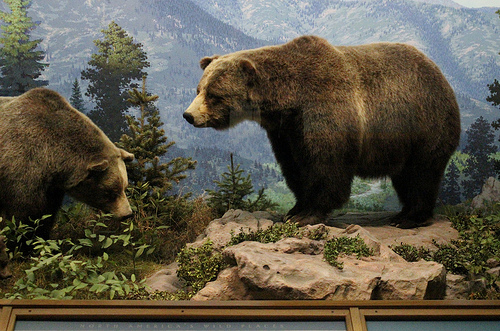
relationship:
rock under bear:
[139, 208, 499, 299] [182, 35, 462, 230]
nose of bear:
[182, 112, 195, 125] [182, 35, 462, 230]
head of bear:
[183, 50, 259, 130] [182, 35, 462, 230]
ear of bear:
[200, 56, 218, 70] [182, 35, 462, 230]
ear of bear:
[238, 58, 258, 75] [182, 35, 462, 230]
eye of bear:
[208, 93, 219, 100] [182, 35, 462, 230]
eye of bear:
[195, 88, 199, 96] [182, 35, 462, 230]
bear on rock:
[182, 35, 462, 230] [139, 208, 499, 299]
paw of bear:
[284, 208, 327, 226] [182, 35, 462, 230]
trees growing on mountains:
[160, 87, 199, 103] [1, 2, 499, 205]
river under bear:
[352, 181, 385, 199] [182, 35, 462, 230]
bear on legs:
[182, 35, 462, 230] [268, 101, 364, 227]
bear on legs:
[182, 35, 462, 230] [389, 143, 456, 227]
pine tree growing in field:
[273, 160, 279, 170] [263, 153, 499, 214]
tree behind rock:
[115, 72, 197, 200] [139, 208, 499, 299]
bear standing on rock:
[182, 35, 462, 230] [139, 208, 499, 299]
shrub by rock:
[436, 215, 495, 298] [139, 208, 499, 299]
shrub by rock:
[175, 241, 223, 299] [139, 208, 499, 299]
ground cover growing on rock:
[325, 234, 366, 272] [139, 208, 499, 299]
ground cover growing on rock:
[223, 222, 327, 248] [139, 208, 499, 299]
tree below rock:
[0, 0, 48, 97] [139, 208, 499, 299]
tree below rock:
[70, 78, 85, 113] [139, 208, 499, 299]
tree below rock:
[115, 72, 197, 200] [139, 208, 499, 299]